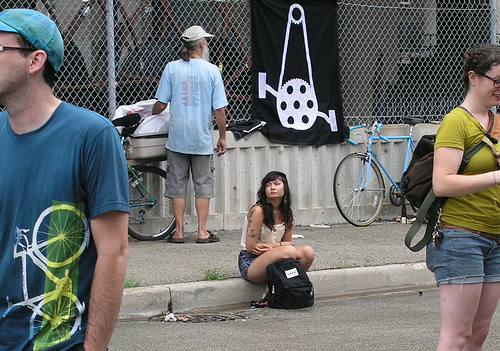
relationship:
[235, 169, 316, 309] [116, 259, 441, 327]
woman sitting on curb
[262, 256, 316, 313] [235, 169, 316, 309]
backpack near woman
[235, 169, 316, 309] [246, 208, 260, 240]
woman has tattoos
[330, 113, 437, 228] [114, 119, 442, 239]
bicycle leaning on wall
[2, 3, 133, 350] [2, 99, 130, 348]
man wears shirt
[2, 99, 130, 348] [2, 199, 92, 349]
shirt has design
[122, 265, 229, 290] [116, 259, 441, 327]
weeds grow on curb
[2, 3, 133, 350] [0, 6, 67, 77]
man wears a hat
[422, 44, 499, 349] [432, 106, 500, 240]
woman wears a shirt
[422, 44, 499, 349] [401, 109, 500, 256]
woman wears backpack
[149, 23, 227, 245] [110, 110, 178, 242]
old man stands near bicycle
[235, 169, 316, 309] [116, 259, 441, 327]
woman sits on curb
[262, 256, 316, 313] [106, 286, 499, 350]
backpack sits on street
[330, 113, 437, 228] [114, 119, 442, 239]
bicycle leans on wall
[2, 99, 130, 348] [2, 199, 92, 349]
shirt has a design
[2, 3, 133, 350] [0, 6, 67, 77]
man has hat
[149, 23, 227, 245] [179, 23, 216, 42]
old man has hat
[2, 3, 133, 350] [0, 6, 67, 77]
man wears hat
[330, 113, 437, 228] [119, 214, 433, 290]
bicycle on sidewalk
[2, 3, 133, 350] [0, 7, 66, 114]
man has head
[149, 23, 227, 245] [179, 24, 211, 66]
old man has head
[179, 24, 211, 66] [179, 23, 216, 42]
head of old man has hat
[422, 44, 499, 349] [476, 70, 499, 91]
woman wears glasses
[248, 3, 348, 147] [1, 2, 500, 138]
banner hanging on fence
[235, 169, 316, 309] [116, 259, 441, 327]
woman sits o curb